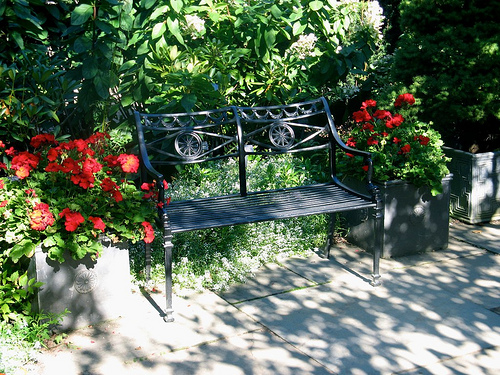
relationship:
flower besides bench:
[117, 153, 140, 173] [156, 110, 397, 244]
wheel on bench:
[168, 119, 298, 159] [129, 95, 384, 324]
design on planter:
[5, 200, 140, 318] [22, 137, 189, 289]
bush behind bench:
[151, 145, 330, 255] [129, 95, 384, 324]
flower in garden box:
[13, 154, 38, 176] [18, 228, 131, 329]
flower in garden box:
[116, 150, 141, 175] [24, 222, 140, 334]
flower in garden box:
[30, 202, 55, 231] [26, 244, 131, 329]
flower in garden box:
[395, 93, 415, 106] [339, 160, 459, 257]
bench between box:
[129, 95, 384, 324] [24, 228, 136, 333]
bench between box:
[129, 95, 384, 324] [337, 166, 453, 262]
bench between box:
[129, 95, 384, 324] [436, 143, 498, 227]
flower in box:
[417, 134, 429, 146] [337, 172, 450, 259]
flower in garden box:
[397, 87, 420, 119] [344, 84, 444, 253]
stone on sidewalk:
[232, 278, 492, 371] [12, 212, 493, 372]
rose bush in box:
[345, 90, 436, 182] [340, 174, 454, 259]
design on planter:
[74, 269, 98, 294] [23, 212, 145, 352]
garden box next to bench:
[26, 244, 131, 329] [132, 95, 390, 296]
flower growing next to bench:
[395, 93, 415, 106] [132, 95, 390, 296]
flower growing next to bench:
[117, 153, 140, 173] [132, 95, 390, 296]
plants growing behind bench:
[58, 9, 350, 91] [86, 59, 389, 296]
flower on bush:
[117, 153, 140, 173] [2, 131, 164, 266]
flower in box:
[395, 93, 415, 106] [340, 174, 454, 259]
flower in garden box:
[7, 132, 157, 269] [26, 244, 131, 329]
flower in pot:
[117, 153, 140, 173] [24, 243, 131, 330]